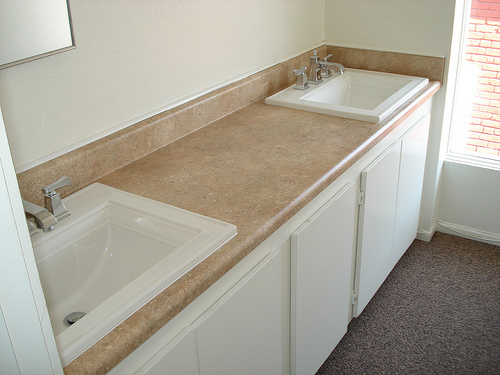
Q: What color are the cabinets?
A: White.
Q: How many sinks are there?
A: Two.